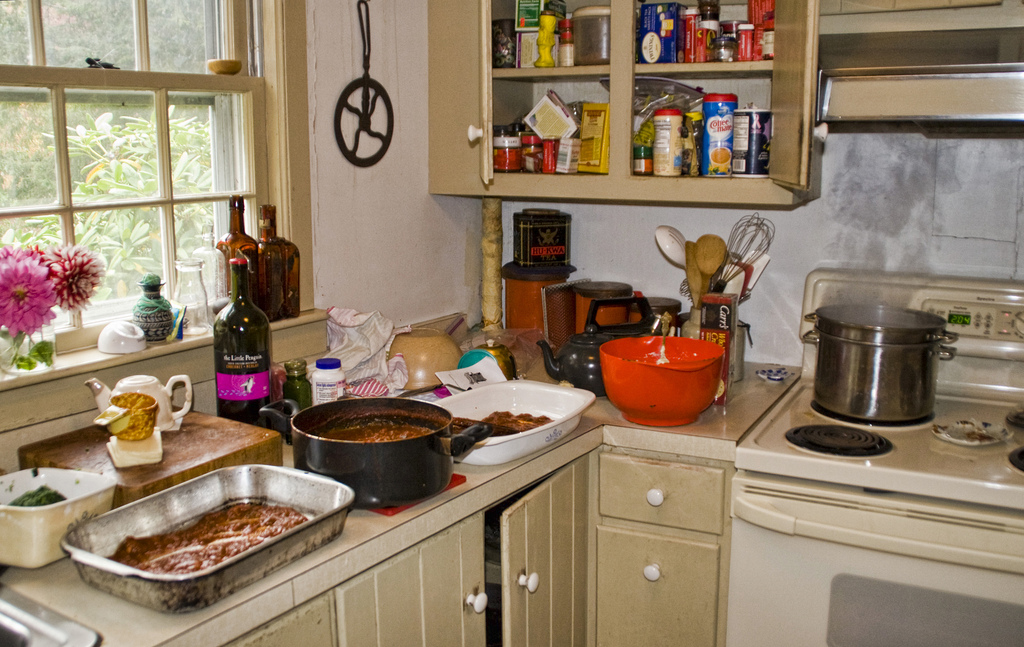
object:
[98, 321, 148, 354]
timer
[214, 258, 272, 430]
bottle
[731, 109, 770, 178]
container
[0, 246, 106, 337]
flowers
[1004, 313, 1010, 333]
lights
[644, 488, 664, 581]
handles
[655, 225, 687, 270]
spoon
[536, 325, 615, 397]
pot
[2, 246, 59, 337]
flower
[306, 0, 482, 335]
wall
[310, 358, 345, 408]
bottle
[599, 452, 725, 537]
drawer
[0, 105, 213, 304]
leaves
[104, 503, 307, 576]
food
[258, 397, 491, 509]
food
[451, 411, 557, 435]
food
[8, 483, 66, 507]
food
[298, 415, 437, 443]
food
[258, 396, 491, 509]
pot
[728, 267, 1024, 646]
oven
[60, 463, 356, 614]
dish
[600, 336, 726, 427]
bowl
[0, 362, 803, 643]
counter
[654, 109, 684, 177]
spice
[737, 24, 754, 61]
spice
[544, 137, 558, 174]
spice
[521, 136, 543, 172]
spice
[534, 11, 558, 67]
spice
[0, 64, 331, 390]
window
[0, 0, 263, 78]
window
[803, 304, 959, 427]
pot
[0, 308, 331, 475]
ledge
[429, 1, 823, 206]
cabinet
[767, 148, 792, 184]
cabinets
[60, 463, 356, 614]
gravy pan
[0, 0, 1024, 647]
kitchen